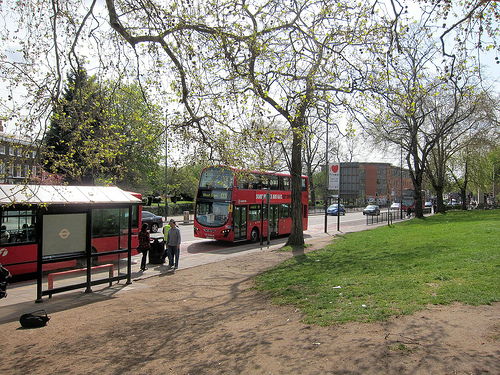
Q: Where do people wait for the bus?
A: Sidewalk.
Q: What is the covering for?
A: A bus stop.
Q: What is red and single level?
A: A bus.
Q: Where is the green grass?
A: In an open area.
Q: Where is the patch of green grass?
A: Next to the sidewalk.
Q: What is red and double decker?
A: A bus.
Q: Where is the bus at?
A: The bus stop.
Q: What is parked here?
A: A red bus.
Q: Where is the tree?
A: Near the sidewalk.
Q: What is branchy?
A: The tree.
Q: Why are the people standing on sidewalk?
A: Waiting for bus.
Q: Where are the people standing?
A: On sidewalk.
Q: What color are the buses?
A: Red.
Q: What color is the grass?
A: Green.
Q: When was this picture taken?
A: During the day.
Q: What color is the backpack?
A: Black.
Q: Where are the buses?
A: On the street.